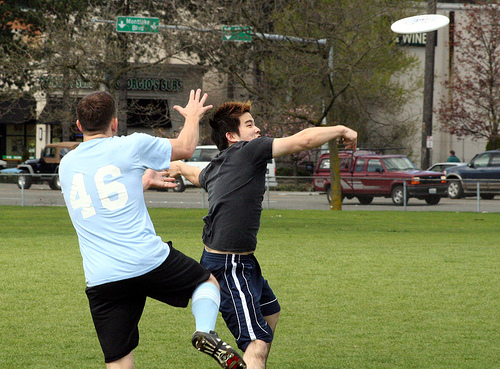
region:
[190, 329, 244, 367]
A cleat being worn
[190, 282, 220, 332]
A light blue shin sock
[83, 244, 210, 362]
A black pair of shorts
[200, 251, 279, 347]
Blue pair of shorts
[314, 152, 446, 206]
A red truck driving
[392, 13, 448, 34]
A white frisbee thrown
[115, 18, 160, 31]
A green street sign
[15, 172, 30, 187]
A black tire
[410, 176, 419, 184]
Front headlight of a truck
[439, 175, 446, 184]
Orange and clear light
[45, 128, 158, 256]
the shirt number is 46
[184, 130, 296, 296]
the shirt is black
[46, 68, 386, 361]
men playing tennis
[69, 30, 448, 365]
men playing tennis in a field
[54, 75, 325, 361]
men playing on a field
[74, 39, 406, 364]
men playing freesbee on the grass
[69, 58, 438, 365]
two men playing freesbee on the grass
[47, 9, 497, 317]
men catching a freesbee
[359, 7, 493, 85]
a freesbee in the air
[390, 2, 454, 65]
a white freesbee in the air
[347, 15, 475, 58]
a freesbe above the grass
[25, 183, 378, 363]
a field of green grass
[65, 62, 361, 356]
two men playing frisbee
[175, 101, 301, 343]
man wearing black shirt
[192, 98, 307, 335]
man wearing blue and white shorts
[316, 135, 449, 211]
red pick up truck with top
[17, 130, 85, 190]
blue jeep with brown top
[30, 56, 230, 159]
store with words on top of building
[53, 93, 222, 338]
man wearing blue shirt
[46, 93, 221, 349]
man wearing black shorts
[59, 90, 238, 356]
man wearing cleats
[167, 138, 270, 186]
white van parked in lot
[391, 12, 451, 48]
white frisbee has been thrown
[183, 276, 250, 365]
guy wearing blue socks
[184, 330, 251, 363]
black/white/red cleat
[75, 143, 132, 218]
shirt reading number 46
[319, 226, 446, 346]
nice green maintaned grass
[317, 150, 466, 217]
red pick-up truck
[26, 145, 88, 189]
black jeep with tan hide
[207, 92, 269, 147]
asian man with multi-colored hair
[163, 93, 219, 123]
mans hand in ''high-five''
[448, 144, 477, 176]
person wearing green in back